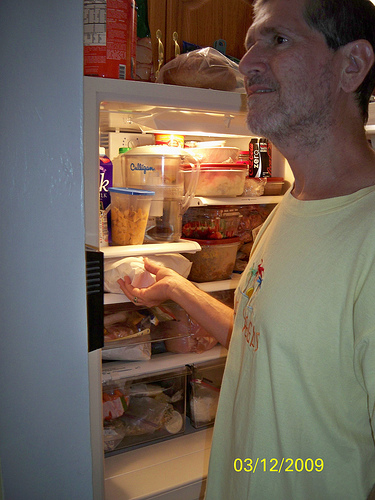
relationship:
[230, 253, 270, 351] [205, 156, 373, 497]
design on shirt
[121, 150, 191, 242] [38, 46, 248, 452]
container in refrigerator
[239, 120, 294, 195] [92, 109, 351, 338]
coke in fridge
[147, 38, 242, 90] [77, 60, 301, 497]
bread in fridge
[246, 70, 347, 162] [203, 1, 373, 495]
hair on man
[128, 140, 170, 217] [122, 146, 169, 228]
milk in container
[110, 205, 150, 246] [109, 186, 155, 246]
left-overs in container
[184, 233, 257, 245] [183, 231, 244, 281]
lid on container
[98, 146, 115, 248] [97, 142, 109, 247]
soy milk in carton